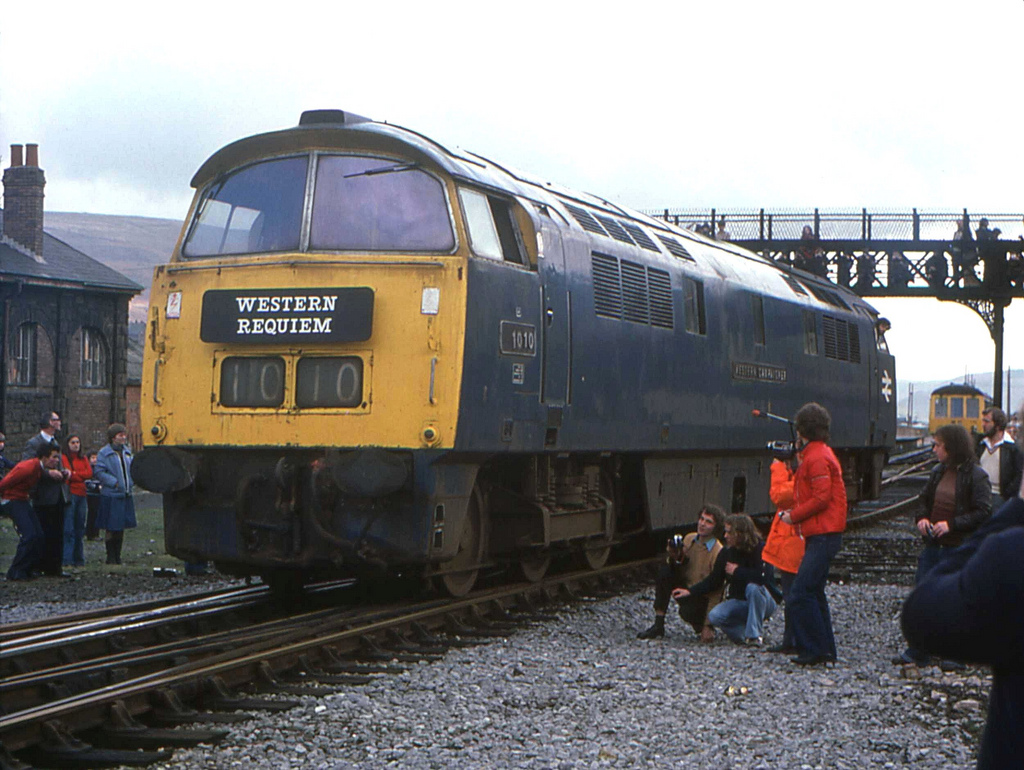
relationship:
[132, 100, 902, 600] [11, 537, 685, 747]
train on track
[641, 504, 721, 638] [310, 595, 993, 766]
person stooping on ground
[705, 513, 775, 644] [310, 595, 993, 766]
person stooping on ground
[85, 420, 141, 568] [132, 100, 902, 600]
person watching train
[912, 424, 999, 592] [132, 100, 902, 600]
lady watching train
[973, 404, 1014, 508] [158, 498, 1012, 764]
man standing on gravel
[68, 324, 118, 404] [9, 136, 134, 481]
window on building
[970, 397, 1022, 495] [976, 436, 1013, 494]
man wearing shirt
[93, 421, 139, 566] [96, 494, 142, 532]
person wearing skirt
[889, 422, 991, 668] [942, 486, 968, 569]
woman with a brown shirt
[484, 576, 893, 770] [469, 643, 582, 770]
gravel that grey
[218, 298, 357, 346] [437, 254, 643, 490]
logo of a train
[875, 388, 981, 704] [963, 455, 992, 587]
woman in a black leather jacket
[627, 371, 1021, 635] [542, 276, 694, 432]
four people looking at a train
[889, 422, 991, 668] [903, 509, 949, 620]
woman holding camera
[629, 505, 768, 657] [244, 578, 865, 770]
two people squatting on ground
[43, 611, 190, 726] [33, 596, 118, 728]
brown metal railroad tracks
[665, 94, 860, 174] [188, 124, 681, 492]
sky above train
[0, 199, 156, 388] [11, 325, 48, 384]
building has windows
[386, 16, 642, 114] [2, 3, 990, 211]
clouds in sky